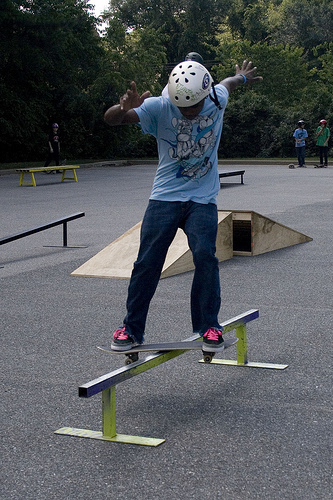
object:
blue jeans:
[124, 196, 223, 343]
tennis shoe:
[201, 333, 224, 352]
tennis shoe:
[111, 324, 138, 348]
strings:
[203, 329, 222, 342]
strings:
[112, 327, 132, 341]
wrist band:
[237, 71, 246, 86]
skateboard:
[311, 163, 324, 168]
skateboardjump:
[16, 165, 80, 187]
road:
[0, 160, 333, 499]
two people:
[293, 120, 331, 168]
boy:
[44, 123, 63, 173]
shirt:
[48, 132, 60, 153]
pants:
[44, 150, 61, 165]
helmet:
[316, 117, 331, 127]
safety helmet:
[296, 120, 305, 126]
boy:
[104, 60, 265, 353]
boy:
[293, 120, 308, 168]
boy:
[315, 119, 331, 167]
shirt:
[132, 83, 229, 205]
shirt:
[293, 129, 308, 148]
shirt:
[315, 126, 330, 146]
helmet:
[165, 60, 213, 107]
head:
[168, 61, 215, 121]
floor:
[287, 163, 295, 169]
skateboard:
[288, 164, 307, 168]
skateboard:
[96, 337, 240, 367]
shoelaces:
[203, 328, 222, 341]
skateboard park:
[0, 163, 333, 500]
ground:
[1, 165, 333, 498]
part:
[53, 426, 166, 448]